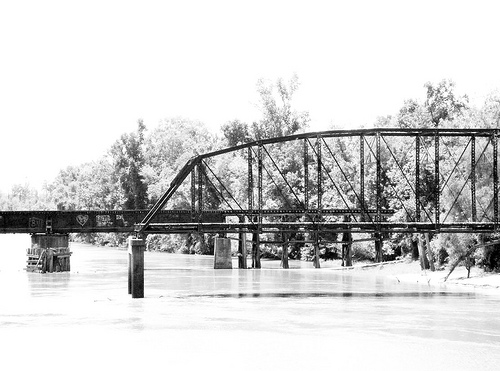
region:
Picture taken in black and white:
[1, 46, 489, 366]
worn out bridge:
[3, 203, 128, 232]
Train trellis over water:
[124, 123, 494, 235]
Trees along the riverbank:
[78, 138, 163, 197]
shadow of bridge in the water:
[203, 282, 462, 298]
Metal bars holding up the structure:
[197, 168, 414, 217]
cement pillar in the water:
[26, 234, 76, 273]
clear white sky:
[28, 73, 84, 143]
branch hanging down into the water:
[443, 255, 484, 282]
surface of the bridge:
[167, 216, 477, 238]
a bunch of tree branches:
[118, 161, 143, 203]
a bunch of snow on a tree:
[60, 163, 105, 193]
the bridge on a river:
[32, 203, 97, 237]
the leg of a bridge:
[120, 229, 158, 291]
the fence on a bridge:
[233, 127, 344, 199]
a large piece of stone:
[210, 235, 245, 275]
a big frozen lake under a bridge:
[312, 283, 382, 330]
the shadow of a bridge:
[269, 265, 312, 315]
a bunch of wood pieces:
[20, 248, 75, 269]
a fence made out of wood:
[238, 232, 328, 268]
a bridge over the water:
[121, 116, 498, 301]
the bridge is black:
[0, 204, 230, 239]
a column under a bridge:
[24, 228, 76, 276]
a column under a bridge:
[208, 230, 238, 272]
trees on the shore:
[0, 61, 497, 279]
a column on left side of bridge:
[119, 227, 151, 299]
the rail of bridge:
[139, 121, 499, 232]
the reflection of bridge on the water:
[170, 278, 481, 310]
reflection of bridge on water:
[21, 265, 76, 302]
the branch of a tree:
[241, 58, 321, 144]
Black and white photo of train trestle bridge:
[13, 0, 496, 369]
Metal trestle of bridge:
[127, 123, 496, 233]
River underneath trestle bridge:
[1, 233, 496, 368]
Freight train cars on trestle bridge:
[1, 206, 226, 233]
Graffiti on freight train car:
[73, 213, 92, 226]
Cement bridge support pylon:
[126, 236, 146, 298]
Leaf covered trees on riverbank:
[0, 75, 499, 257]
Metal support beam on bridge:
[313, 138, 325, 226]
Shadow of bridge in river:
[182, 293, 498, 300]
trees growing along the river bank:
[3, 70, 497, 264]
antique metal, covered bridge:
[119, 118, 498, 306]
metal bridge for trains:
[0, 198, 397, 240]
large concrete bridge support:
[21, 228, 79, 278]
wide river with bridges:
[7, 231, 498, 368]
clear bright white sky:
[0, 0, 499, 191]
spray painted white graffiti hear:
[73, 211, 93, 228]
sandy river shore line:
[303, 245, 498, 304]